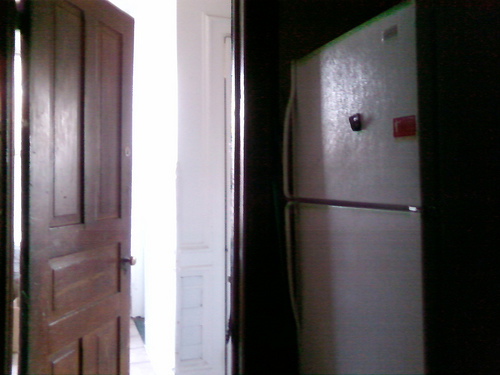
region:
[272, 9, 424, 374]
a white refrigerator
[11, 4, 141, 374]
a brown door is open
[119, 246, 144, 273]
door knob in a brown door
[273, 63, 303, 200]
a handle of freezer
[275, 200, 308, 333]
a handle of freezer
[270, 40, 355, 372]
shadow cast on refrigerator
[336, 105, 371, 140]
a black magnet on refrigerator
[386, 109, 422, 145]
a red magnet on refrigerator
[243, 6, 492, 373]
refrigerator is in a black room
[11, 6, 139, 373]
an open door color brown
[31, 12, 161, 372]
The door is open.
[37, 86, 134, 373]
The door is brown.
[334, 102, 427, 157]
Magnets on the refrigerator.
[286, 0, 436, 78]
Green line on top of the refrigerator.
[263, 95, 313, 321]
There are two handles.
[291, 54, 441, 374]
The refrigerator is white.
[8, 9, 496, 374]
Taken in a kitchen.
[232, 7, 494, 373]
Taken in the dark.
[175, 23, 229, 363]
The door is white.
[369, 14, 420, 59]
Decal on the refrigerator.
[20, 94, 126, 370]
this is a door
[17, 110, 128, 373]
the door is wooden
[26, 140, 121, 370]
the door is brown in color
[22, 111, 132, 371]
the door is big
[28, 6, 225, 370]
the door is open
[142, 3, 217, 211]
this is the wall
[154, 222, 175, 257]
the wall is white in color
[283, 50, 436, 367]
this is a fridge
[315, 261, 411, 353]
the fridge is metallic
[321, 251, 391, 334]
the fridge is white in color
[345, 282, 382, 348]
part of a fridge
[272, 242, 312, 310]
part of a handle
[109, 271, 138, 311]
edge of a door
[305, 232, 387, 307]
part of a shade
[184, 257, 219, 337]
poart of a door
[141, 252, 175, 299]
edge of a door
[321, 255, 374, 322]
part of a shade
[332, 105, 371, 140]
a blue magnet on the door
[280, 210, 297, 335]
handle on the refrigerator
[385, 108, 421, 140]
red square on the refrigerator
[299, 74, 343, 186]
white freezer door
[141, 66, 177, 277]
bright light shining through the doorway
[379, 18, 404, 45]
company tag on the refrigerator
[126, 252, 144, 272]
yellow brass door knob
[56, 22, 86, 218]
square panel in the door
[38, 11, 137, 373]
brown wooden door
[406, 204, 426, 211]
metal hing on the door